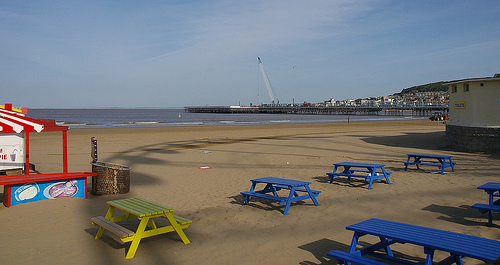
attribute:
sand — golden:
[0, 121, 499, 261]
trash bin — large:
[91, 158, 133, 196]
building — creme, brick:
[446, 78, 498, 139]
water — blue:
[108, 92, 418, 136]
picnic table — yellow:
[84, 193, 195, 259]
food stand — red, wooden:
[13, 111, 128, 198]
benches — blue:
[243, 141, 498, 263]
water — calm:
[90, 110, 177, 120]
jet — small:
[250, 52, 265, 67]